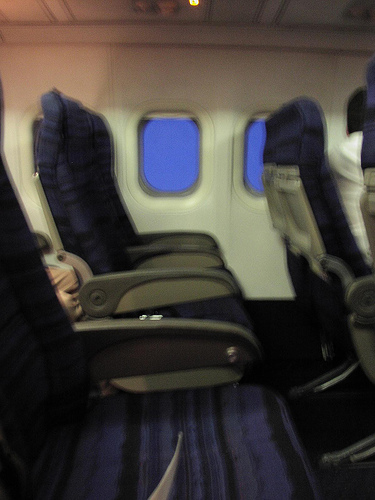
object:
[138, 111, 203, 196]
window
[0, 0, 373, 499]
airplane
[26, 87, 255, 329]
seat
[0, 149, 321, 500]
seat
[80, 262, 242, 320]
armrest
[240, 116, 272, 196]
window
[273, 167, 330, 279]
tray table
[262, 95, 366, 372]
seat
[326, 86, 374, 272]
passenger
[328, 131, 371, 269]
shirt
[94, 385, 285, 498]
carpet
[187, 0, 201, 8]
light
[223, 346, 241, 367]
button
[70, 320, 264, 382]
armrest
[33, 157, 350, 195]
row